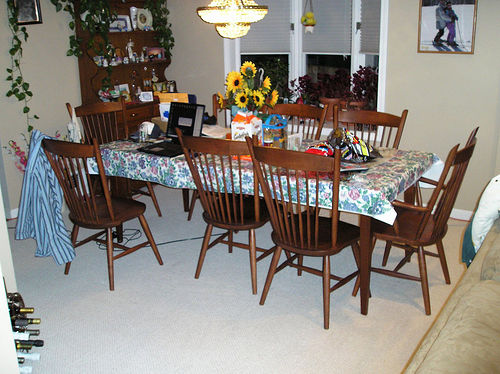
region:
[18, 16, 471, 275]
a dining room area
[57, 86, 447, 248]
a dining room table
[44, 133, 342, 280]
dining room chairs at the table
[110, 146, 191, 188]
a flower print table cloth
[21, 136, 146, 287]
clothes on the chair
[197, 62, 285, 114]
flowers on the table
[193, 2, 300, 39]
alight above the table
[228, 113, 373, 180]
items on the table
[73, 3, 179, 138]
a book case in the dining room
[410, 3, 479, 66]
a picture on the wall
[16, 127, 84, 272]
blue striped button down shirt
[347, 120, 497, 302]
brown wooden chair at head of table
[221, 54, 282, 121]
bouquet of daisies on table top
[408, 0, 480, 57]
photo of people on wall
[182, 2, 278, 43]
glass and gold chandelier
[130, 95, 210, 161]
laptop computer on table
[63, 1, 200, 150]
brown wooden china hutch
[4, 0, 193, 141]
long green ivy plant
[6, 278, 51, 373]
wine bottle necks jutting out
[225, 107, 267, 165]
goldfish crackers carton on table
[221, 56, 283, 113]
Bunch of sunflowers with dark green leaves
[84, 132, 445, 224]
White tablecloth with flower patterns on it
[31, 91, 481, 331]
Wooden table with eight chairs around it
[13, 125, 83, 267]
Blue and grey striped shirt hanging from chair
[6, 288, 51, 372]
Bottles of alcohol stacked on top of each other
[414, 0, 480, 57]
Framed photograph on the wall of people in the snow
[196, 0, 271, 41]
Lit-up light fixture with golden bands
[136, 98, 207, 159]
Black laptop computer with open lid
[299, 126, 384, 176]
Pile of black and red bags of chips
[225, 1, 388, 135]
Window with three panes and half closed blinds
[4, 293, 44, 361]
Tops of wine bottles on shelf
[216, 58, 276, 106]
Yellow sunflowers on table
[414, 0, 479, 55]
Framed picture on wall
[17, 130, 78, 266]
Blue striped shirt on chair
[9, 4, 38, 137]
Green leafy vine on wall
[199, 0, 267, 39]
Brightly lit light over table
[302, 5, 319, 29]
Hanging basket of fruit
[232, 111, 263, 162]
Orange carton of goldfish crackers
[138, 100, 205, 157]
Black laptop on table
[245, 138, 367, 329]
Brown chair with rungs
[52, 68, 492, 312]
Table is relatively long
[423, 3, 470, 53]
Skiing trip picture in background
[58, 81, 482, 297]
Many chairs around table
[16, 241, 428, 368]
Floor is light tan color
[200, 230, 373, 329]
Legs of two chairs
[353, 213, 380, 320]
One leg of table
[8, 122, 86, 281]
Shirt hanging on chair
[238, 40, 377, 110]
Windows behind table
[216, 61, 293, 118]
Sunflowers on table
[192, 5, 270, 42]
Yellow light above table